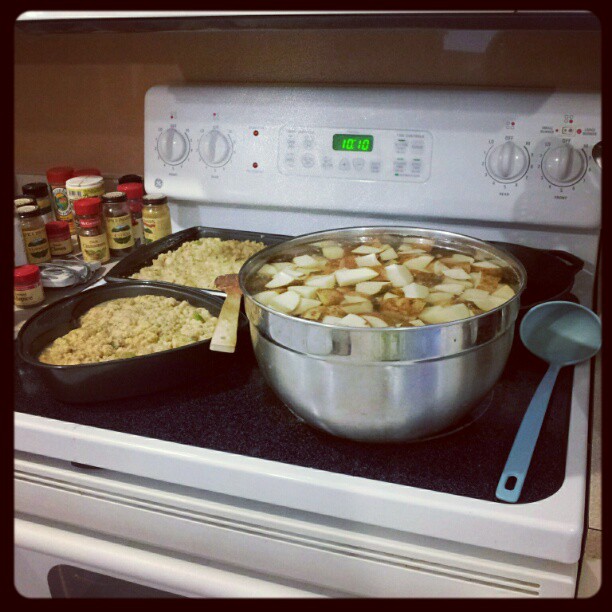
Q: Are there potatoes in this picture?
A: Yes, there is a potato.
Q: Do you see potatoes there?
A: Yes, there is a potato.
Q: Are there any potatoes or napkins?
A: Yes, there is a potato.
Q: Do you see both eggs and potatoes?
A: No, there is a potato but no eggs.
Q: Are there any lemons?
A: No, there are no lemons.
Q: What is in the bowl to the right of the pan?
A: The potato is in the bowl.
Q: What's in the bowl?
A: The potato is in the bowl.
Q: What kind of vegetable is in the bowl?
A: The vegetable is a potato.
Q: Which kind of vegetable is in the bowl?
A: The vegetable is a potato.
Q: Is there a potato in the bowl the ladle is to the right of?
A: Yes, there is a potato in the bowl.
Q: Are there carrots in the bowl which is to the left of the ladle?
A: No, there is a potato in the bowl.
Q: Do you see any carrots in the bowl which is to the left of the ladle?
A: No, there is a potato in the bowl.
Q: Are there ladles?
A: Yes, there is a ladle.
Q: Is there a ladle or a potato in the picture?
A: Yes, there is a ladle.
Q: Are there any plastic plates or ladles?
A: Yes, there is a plastic ladle.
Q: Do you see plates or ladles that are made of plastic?
A: Yes, the ladle is made of plastic.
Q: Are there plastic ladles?
A: Yes, there is a ladle that is made of plastic.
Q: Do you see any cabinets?
A: No, there are no cabinets.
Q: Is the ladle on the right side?
A: Yes, the ladle is on the right of the image.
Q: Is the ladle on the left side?
A: No, the ladle is on the right of the image.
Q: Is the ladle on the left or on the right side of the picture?
A: The ladle is on the right of the image.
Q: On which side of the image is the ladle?
A: The ladle is on the right of the image.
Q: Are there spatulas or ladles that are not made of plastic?
A: No, there is a ladle but it is made of plastic.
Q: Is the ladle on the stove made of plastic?
A: Yes, the ladle is made of plastic.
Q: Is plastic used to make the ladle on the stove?
A: Yes, the ladle is made of plastic.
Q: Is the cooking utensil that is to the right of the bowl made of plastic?
A: Yes, the ladle is made of plastic.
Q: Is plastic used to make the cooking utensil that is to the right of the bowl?
A: Yes, the ladle is made of plastic.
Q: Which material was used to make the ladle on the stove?
A: The ladle is made of plastic.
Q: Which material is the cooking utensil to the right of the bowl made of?
A: The ladle is made of plastic.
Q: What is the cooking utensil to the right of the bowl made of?
A: The ladle is made of plastic.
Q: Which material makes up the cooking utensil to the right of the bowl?
A: The ladle is made of plastic.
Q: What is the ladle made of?
A: The ladle is made of plastic.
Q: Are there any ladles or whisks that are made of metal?
A: No, there is a ladle but it is made of plastic.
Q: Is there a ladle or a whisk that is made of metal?
A: No, there is a ladle but it is made of plastic.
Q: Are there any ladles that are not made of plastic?
A: No, there is a ladle but it is made of plastic.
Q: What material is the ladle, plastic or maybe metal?
A: The ladle is made of plastic.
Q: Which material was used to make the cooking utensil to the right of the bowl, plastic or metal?
A: The ladle is made of plastic.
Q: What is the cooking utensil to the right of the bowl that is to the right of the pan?
A: The cooking utensil is a ladle.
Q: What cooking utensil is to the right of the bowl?
A: The cooking utensil is a ladle.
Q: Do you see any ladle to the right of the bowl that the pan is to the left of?
A: Yes, there is a ladle to the right of the bowl.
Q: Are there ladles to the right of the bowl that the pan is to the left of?
A: Yes, there is a ladle to the right of the bowl.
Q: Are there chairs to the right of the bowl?
A: No, there is a ladle to the right of the bowl.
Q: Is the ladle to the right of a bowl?
A: Yes, the ladle is to the right of a bowl.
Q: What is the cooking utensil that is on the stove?
A: The cooking utensil is a ladle.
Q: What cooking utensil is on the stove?
A: The cooking utensil is a ladle.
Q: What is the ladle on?
A: The ladle is on the stove.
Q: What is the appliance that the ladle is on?
A: The appliance is a stove.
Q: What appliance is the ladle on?
A: The ladle is on the stove.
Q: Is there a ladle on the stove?
A: Yes, there is a ladle on the stove.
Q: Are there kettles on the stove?
A: No, there is a ladle on the stove.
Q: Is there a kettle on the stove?
A: No, there is a ladle on the stove.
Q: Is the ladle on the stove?
A: Yes, the ladle is on the stove.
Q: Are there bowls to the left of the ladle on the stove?
A: Yes, there is a bowl to the left of the ladle.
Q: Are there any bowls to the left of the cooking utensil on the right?
A: Yes, there is a bowl to the left of the ladle.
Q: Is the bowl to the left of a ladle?
A: Yes, the bowl is to the left of a ladle.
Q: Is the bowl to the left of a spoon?
A: No, the bowl is to the left of a ladle.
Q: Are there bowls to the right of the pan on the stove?
A: Yes, there is a bowl to the right of the pan.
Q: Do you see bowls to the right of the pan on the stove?
A: Yes, there is a bowl to the right of the pan.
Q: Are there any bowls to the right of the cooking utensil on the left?
A: Yes, there is a bowl to the right of the pan.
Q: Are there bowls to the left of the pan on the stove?
A: No, the bowl is to the right of the pan.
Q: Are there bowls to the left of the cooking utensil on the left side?
A: No, the bowl is to the right of the pan.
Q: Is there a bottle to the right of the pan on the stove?
A: No, there is a bowl to the right of the pan.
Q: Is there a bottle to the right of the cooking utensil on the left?
A: No, there is a bowl to the right of the pan.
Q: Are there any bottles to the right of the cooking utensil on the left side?
A: No, there is a bowl to the right of the pan.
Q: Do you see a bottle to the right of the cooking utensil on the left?
A: No, there is a bowl to the right of the pan.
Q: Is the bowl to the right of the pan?
A: Yes, the bowl is to the right of the pan.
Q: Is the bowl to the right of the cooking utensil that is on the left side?
A: Yes, the bowl is to the right of the pan.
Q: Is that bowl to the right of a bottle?
A: No, the bowl is to the right of the pan.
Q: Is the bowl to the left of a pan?
A: No, the bowl is to the right of a pan.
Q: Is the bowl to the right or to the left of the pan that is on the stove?
A: The bowl is to the right of the pan.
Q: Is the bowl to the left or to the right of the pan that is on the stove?
A: The bowl is to the right of the pan.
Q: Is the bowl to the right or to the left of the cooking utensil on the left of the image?
A: The bowl is to the right of the pan.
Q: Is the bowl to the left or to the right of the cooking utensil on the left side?
A: The bowl is to the right of the pan.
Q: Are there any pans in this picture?
A: Yes, there is a pan.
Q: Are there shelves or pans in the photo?
A: Yes, there is a pan.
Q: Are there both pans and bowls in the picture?
A: Yes, there are both a pan and a bowl.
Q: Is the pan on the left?
A: Yes, the pan is on the left of the image.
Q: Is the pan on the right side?
A: No, the pan is on the left of the image.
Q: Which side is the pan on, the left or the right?
A: The pan is on the left of the image.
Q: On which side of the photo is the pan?
A: The pan is on the left of the image.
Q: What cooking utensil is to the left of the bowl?
A: The cooking utensil is a pan.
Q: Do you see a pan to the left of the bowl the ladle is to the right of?
A: Yes, there is a pan to the left of the bowl.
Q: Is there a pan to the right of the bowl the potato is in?
A: No, the pan is to the left of the bowl.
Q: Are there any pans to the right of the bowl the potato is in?
A: No, the pan is to the left of the bowl.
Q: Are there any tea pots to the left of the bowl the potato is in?
A: No, there is a pan to the left of the bowl.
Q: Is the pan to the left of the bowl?
A: Yes, the pan is to the left of the bowl.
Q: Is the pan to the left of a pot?
A: No, the pan is to the left of the bowl.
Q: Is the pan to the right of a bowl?
A: No, the pan is to the left of a bowl.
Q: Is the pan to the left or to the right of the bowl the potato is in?
A: The pan is to the left of the bowl.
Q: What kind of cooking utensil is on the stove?
A: The cooking utensil is a pan.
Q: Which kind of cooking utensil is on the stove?
A: The cooking utensil is a pan.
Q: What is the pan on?
A: The pan is on the stove.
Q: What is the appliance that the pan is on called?
A: The appliance is a stove.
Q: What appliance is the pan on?
A: The pan is on the stove.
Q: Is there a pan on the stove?
A: Yes, there is a pan on the stove.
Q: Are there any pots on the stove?
A: No, there is a pan on the stove.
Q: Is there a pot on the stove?
A: No, there is a pan on the stove.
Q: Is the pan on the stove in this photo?
A: Yes, the pan is on the stove.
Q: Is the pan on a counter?
A: No, the pan is on the stove.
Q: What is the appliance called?
A: The appliance is a stove.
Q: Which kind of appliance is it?
A: The appliance is a stove.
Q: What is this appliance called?
A: This is a stove.